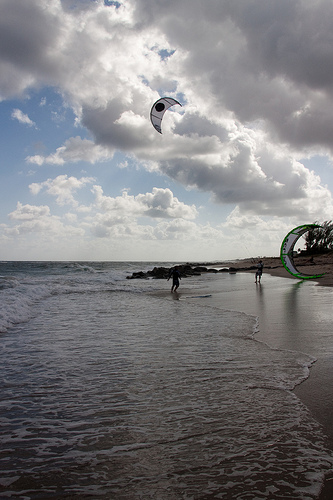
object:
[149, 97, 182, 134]
parasail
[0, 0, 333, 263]
sky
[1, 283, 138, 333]
wave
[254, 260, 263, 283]
person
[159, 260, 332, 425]
beach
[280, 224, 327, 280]
parasail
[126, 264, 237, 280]
rocks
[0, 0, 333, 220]
cloud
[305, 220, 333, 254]
tree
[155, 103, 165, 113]
circle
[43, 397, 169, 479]
sea foam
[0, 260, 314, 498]
water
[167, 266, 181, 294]
person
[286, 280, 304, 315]
shadow